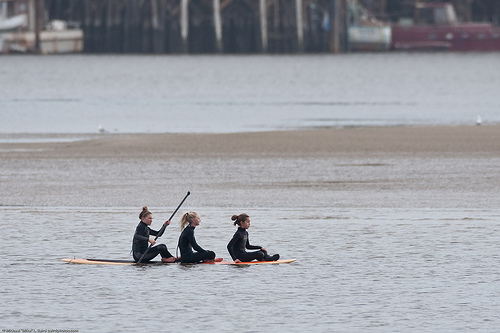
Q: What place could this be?
A: It is a sea.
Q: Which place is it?
A: It is a sea.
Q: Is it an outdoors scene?
A: Yes, it is outdoors.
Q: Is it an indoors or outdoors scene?
A: It is outdoors.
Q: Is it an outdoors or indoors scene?
A: It is outdoors.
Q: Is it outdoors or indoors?
A: It is outdoors.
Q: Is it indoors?
A: No, it is outdoors.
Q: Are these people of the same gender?
A: Yes, all the people are female.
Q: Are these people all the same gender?
A: Yes, all the people are female.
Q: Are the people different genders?
A: No, all the people are female.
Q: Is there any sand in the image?
A: Yes, there is sand.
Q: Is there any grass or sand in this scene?
A: Yes, there is sand.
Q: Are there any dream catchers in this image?
A: No, there are no dream catchers.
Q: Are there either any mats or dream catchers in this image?
A: No, there are no dream catchers or mats.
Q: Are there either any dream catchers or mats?
A: No, there are no dream catchers or mats.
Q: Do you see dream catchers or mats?
A: No, there are no dream catchers or mats.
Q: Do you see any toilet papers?
A: No, there are no toilet papers.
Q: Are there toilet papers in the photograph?
A: No, there are no toilet papers.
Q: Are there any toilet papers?
A: No, there are no toilet papers.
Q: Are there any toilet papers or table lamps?
A: No, there are no toilet papers or table lamps.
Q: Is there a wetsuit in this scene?
A: Yes, there is a wetsuit.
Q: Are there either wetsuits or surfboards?
A: Yes, there is a wetsuit.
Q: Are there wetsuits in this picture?
A: Yes, there is a wetsuit.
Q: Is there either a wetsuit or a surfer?
A: Yes, there is a wetsuit.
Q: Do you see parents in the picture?
A: No, there are no parents.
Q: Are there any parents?
A: No, there are no parents.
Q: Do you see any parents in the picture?
A: No, there are no parents.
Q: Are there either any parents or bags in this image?
A: No, there are no parents or bags.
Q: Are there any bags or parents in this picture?
A: No, there are no parents or bags.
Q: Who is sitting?
A: The girls are sitting.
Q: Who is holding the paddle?
A: The girls are holding the paddle.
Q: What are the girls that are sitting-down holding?
A: The girls are holding the oar.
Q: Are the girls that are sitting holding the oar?
A: Yes, the girls are holding the oar.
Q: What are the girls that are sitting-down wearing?
A: The girls are wearing a wetsuit.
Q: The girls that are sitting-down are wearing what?
A: The girls are wearing a wetsuit.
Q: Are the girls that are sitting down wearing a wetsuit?
A: Yes, the girls are wearing a wetsuit.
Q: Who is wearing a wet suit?
A: The girls are wearing a wet suit.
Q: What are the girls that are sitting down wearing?
A: The girls are wearing a wetsuit.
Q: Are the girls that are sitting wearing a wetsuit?
A: Yes, the girls are wearing a wetsuit.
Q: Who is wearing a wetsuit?
A: The girls are wearing a wetsuit.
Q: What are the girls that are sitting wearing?
A: The girls are wearing a wetsuit.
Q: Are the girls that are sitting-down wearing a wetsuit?
A: Yes, the girls are wearing a wetsuit.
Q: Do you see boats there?
A: Yes, there is a boat.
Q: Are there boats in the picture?
A: Yes, there is a boat.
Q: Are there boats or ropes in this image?
A: Yes, there is a boat.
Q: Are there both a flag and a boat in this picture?
A: No, there is a boat but no flags.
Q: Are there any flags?
A: No, there are no flags.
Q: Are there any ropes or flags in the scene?
A: No, there are no flags or ropes.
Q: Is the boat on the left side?
A: No, the boat is on the right of the image.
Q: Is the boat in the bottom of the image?
A: No, the boat is in the top of the image.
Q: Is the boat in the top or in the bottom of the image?
A: The boat is in the top of the image.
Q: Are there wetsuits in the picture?
A: Yes, there is a wetsuit.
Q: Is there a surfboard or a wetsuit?
A: Yes, there is a wetsuit.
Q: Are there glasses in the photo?
A: No, there are no glasses.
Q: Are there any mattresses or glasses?
A: No, there are no glasses or mattresses.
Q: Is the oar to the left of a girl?
A: Yes, the oar is to the left of a girl.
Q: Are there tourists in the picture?
A: No, there are no tourists.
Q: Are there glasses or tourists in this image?
A: No, there are no tourists or glasses.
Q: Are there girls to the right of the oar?
A: Yes, there is a girl to the right of the oar.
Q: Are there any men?
A: No, there are no men.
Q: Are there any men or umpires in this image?
A: No, there are no men or umpires.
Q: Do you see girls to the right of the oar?
A: Yes, there is a girl to the right of the oar.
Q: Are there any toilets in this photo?
A: No, there are no toilets.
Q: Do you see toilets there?
A: No, there are no toilets.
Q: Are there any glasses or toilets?
A: No, there are no toilets or glasses.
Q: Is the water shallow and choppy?
A: Yes, the water is shallow and choppy.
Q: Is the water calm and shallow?
A: No, the water is shallow but choppy.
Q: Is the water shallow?
A: Yes, the water is shallow.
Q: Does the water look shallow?
A: Yes, the water is shallow.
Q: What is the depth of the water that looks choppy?
A: The water is shallow.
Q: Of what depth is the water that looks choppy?
A: The water is shallow.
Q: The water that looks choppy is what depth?
A: The water is shallow.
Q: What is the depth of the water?
A: The water is shallow.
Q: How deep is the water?
A: The water is shallow.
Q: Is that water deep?
A: No, the water is shallow.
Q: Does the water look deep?
A: No, the water is shallow.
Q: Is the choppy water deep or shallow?
A: The water is shallow.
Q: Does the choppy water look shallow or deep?
A: The water is shallow.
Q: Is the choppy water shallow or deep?
A: The water is shallow.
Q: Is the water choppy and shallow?
A: Yes, the water is choppy and shallow.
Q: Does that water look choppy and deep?
A: No, the water is choppy but shallow.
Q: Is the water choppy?
A: Yes, the water is choppy.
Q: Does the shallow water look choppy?
A: Yes, the water is choppy.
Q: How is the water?
A: The water is choppy.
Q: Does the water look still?
A: No, the water is choppy.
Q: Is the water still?
A: No, the water is choppy.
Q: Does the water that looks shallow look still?
A: No, the water is choppy.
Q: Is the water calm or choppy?
A: The water is choppy.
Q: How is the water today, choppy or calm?
A: The water is choppy.